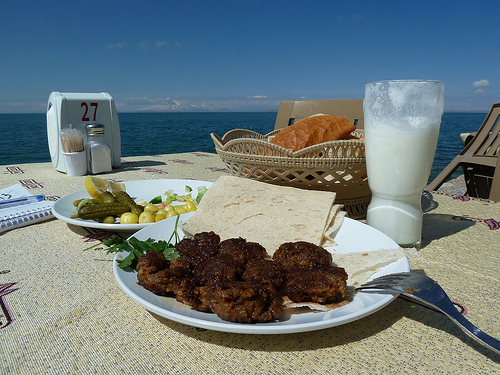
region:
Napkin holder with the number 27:
[43, 85, 125, 176]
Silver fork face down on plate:
[354, 259, 499, 359]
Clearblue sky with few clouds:
[1, 0, 497, 113]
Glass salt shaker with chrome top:
[77, 115, 121, 180]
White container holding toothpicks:
[56, 124, 95, 181]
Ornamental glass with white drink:
[358, 75, 447, 251]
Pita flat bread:
[178, 170, 408, 319]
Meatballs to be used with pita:
[138, 233, 355, 333]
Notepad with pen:
[0, 175, 68, 243]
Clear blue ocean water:
[0, 113, 497, 165]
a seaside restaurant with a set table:
[13, 18, 493, 371]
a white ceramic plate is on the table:
[110, 201, 410, 338]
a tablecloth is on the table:
[2, 153, 499, 373]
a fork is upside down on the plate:
[353, 270, 499, 365]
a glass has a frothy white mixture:
[356, 78, 446, 249]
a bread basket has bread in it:
[207, 111, 386, 203]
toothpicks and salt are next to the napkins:
[45, 90, 124, 174]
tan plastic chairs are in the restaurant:
[274, 91, 499, 197]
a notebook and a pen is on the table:
[2, 182, 57, 234]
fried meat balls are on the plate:
[133, 224, 348, 322]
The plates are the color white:
[52, 175, 422, 334]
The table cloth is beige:
[18, 245, 108, 362]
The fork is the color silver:
[356, 263, 499, 365]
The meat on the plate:
[146, 230, 347, 320]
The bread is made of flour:
[201, 173, 337, 248]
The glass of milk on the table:
[358, 78, 447, 255]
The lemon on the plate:
[79, 170, 131, 197]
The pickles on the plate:
[68, 186, 141, 222]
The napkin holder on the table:
[41, 89, 133, 173]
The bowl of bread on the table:
[204, 111, 399, 223]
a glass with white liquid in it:
[349, 73, 470, 263]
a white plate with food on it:
[115, 180, 427, 347]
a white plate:
[125, 173, 415, 365]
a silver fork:
[354, 262, 498, 357]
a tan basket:
[182, 79, 416, 227]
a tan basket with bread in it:
[191, 100, 410, 205]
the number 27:
[68, 90, 112, 125]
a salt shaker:
[48, 113, 122, 204]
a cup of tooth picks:
[37, 112, 95, 182]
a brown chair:
[436, 75, 496, 203]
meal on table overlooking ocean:
[12, 26, 487, 356]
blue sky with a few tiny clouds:
[0, 5, 490, 95]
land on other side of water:
[0, 90, 495, 105]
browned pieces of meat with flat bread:
[115, 175, 410, 335]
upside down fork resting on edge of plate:
[355, 255, 490, 355]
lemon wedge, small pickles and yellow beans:
[45, 170, 205, 225]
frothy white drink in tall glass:
[360, 70, 445, 245]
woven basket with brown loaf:
[205, 90, 365, 195]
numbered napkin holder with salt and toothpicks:
[41, 85, 129, 175]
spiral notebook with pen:
[0, 170, 55, 235]